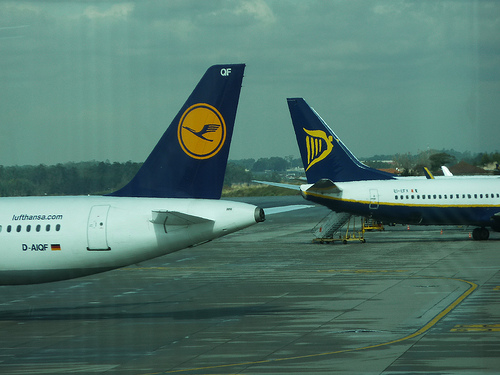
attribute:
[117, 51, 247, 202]
fin — blue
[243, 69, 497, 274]
airplane — blue, white, yellow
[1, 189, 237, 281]
airplane — large 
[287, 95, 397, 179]
tail — blue  , white   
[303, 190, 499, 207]
stripe — yellow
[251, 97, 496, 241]
plane — together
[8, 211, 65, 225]
lettering — black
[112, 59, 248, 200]
blue tail — white , blue  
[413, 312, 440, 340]
lines — yellow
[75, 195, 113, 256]
door — rear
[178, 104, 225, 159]
logo — orange, blue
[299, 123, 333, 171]
logo — yellow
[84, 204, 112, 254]
door — closed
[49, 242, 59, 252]
flag — small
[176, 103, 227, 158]
yellow logo — round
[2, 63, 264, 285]
plane — white, blue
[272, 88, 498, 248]
airplane — large 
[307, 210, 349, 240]
stair case — portable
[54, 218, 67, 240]
window — small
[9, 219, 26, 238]
window — small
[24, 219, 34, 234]
window — small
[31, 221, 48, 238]
window — small